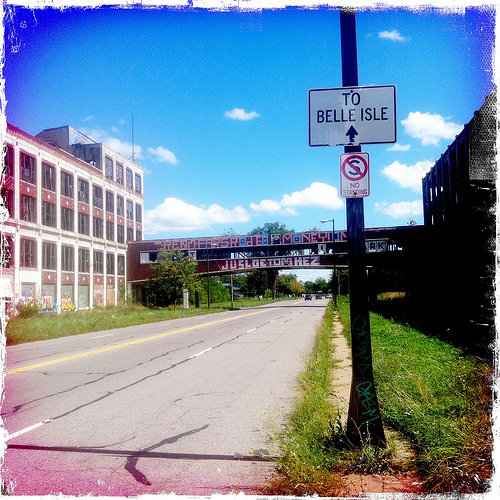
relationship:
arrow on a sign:
[342, 121, 360, 150] [309, 105, 386, 152]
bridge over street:
[134, 208, 327, 274] [170, 292, 321, 358]